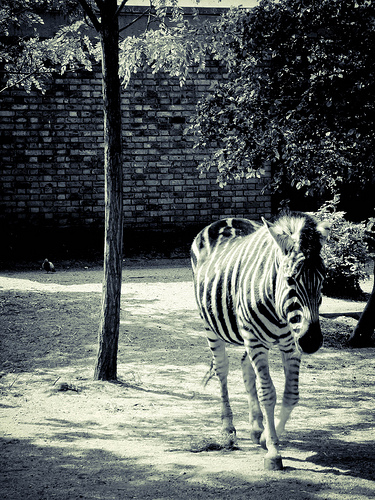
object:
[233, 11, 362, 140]
forest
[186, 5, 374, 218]
trees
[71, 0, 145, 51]
branches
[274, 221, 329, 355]
head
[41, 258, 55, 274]
bird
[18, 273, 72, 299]
dirt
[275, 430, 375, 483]
shadow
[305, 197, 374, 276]
plants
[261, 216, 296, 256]
ears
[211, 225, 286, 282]
black and white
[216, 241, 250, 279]
lines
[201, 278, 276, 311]
black stripes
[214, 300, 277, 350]
white stripes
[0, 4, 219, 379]
tree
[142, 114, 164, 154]
wall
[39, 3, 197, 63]
sun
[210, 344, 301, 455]
four legs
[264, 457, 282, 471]
hoofs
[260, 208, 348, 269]
two ears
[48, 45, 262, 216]
pen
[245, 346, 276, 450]
front legs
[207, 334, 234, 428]
back legs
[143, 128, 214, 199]
brick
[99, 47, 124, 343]
trunk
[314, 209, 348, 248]
left ear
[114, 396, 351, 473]
ground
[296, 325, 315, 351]
muzzle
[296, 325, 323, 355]
nostrils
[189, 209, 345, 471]
animal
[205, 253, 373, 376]
way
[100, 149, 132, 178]
thin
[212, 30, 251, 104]
leaves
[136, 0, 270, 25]
top ledge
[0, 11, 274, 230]
brick wall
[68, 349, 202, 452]
dirt field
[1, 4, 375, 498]
zoo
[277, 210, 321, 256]
head up